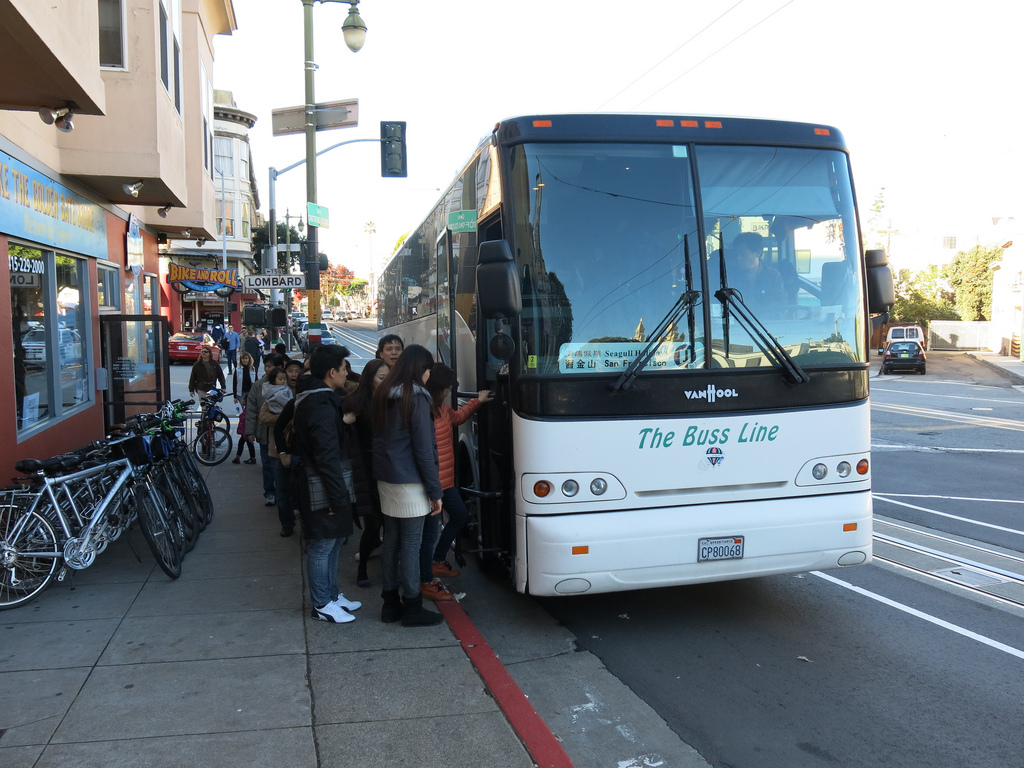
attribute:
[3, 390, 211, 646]
bicycles — ROW, PARKED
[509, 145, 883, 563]
bus — COMMUTER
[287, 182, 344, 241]
sign — STREET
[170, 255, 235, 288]
sign — BLUE, ORANGE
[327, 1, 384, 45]
lamp — STREET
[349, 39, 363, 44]
globe — FROSTED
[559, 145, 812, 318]
window — BUS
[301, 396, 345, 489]
jacket — DARK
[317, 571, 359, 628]
sneakers — WHITE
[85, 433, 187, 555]
bicycles — ROW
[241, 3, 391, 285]
light — TALL, STREET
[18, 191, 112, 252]
sign — BLUE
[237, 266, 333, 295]
sign — WHITE, STREET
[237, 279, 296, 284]
letters — BLACK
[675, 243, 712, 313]
seat — DRIVERS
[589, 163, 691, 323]
glass — VIEW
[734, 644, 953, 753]
road — VIEW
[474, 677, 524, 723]
line — VIEW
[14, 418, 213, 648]
cycles — VIEW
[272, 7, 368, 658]
pole — view 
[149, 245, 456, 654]
passengers — group 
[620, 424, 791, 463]
bus — name 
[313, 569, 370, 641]
person — shoe 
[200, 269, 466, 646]
people — several 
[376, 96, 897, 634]
bus — black , large white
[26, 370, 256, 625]
bikes — parked , row 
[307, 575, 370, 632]
shoes — black , white 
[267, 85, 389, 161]
sign — white , green 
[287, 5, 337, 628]
pole — black , white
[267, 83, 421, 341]
sign — Roll , Bike 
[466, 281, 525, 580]
doors — open glass 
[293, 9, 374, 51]
light — traffic ,  back side 